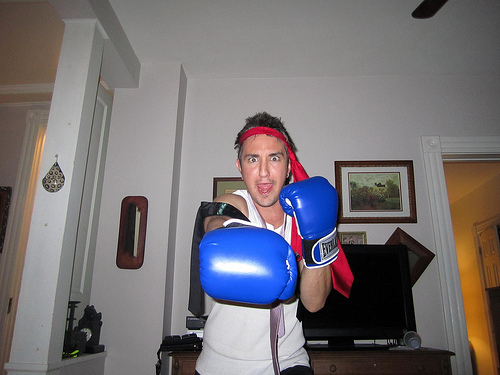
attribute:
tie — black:
[185, 198, 244, 320]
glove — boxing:
[279, 177, 349, 276]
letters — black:
[316, 232, 343, 264]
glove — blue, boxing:
[274, 178, 343, 272]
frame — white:
[421, 134, 497, 373]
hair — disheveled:
[232, 110, 290, 137]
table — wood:
[167, 345, 457, 373]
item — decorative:
[41, 148, 66, 194]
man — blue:
[182, 106, 347, 373]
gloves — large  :
[194, 168, 345, 308]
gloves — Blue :
[177, 173, 365, 310]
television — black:
[264, 221, 437, 352]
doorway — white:
[416, 132, 499, 374]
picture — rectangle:
[334, 151, 422, 225]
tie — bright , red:
[235, 124, 360, 301]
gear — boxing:
[175, 171, 362, 322]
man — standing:
[184, 112, 359, 374]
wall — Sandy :
[73, 19, 497, 152]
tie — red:
[221, 114, 309, 169]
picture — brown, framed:
[331, 155, 418, 228]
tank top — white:
[188, 181, 343, 373]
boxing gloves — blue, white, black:
[203, 178, 338, 308]